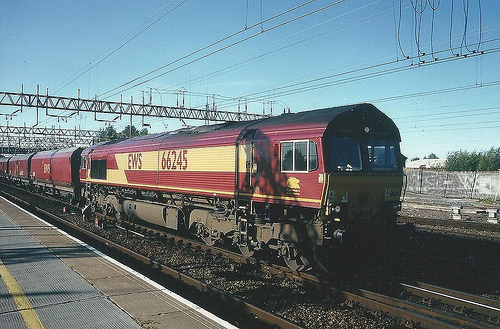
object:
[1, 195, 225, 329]
platform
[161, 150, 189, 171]
numbers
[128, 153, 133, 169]
letters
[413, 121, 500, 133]
wires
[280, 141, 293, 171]
window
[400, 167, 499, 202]
wall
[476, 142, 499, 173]
tree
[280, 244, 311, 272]
wheels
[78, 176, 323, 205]
stripe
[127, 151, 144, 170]
logo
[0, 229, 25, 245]
bricks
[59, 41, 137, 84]
lines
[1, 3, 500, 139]
sky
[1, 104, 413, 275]
railroad car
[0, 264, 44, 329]
line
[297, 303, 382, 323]
gravel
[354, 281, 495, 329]
track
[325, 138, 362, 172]
window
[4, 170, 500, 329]
railway station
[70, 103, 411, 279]
engine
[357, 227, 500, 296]
shadow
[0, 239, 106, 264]
shadow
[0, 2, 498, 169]
background